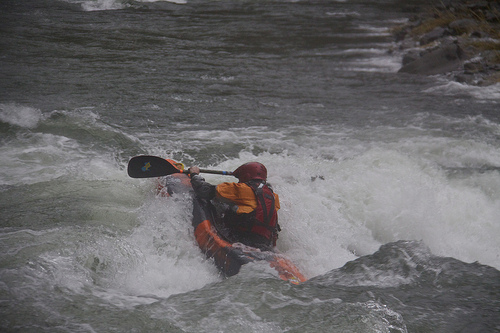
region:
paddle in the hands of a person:
[129, 152, 237, 178]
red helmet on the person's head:
[237, 159, 265, 178]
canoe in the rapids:
[182, 164, 302, 281]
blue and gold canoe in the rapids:
[190, 176, 305, 288]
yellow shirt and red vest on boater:
[213, 183, 279, 243]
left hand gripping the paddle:
[187, 165, 199, 173]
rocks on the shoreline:
[390, 16, 497, 88]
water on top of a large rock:
[16, 240, 497, 331]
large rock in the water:
[25, 238, 497, 331]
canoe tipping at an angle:
[192, 171, 302, 283]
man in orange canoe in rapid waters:
[122, 134, 312, 302]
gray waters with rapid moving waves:
[5, 2, 491, 324]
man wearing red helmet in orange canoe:
[230, 159, 269, 181]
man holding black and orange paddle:
[116, 147, 248, 183]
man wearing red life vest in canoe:
[230, 183, 281, 242]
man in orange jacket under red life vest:
[192, 178, 287, 244]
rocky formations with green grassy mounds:
[345, 9, 499, 98]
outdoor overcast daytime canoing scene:
[11, 0, 496, 326]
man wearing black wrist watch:
[187, 173, 202, 175]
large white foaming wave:
[17, 115, 493, 319]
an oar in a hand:
[119, 147, 239, 182]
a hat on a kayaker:
[233, 154, 269, 196]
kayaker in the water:
[129, 136, 314, 310]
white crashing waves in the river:
[310, 163, 389, 236]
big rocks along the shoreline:
[408, 15, 483, 98]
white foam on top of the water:
[16, 88, 119, 173]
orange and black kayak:
[185, 203, 321, 300]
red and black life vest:
[230, 182, 288, 232]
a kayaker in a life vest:
[193, 161, 294, 253]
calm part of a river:
[147, 22, 242, 64]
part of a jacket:
[258, 157, 263, 172]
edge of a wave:
[337, 245, 344, 266]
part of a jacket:
[256, 187, 261, 208]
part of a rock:
[353, 90, 384, 152]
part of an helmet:
[244, 177, 246, 178]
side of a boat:
[271, 255, 286, 281]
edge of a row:
[180, 173, 191, 192]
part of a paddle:
[209, 179, 210, 194]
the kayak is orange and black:
[162, 153, 309, 290]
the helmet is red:
[234, 162, 279, 184]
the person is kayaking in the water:
[105, 106, 329, 282]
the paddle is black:
[125, 151, 233, 186]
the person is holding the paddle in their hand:
[124, 148, 282, 250]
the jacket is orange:
[213, 182, 282, 225]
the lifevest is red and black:
[245, 179, 280, 245]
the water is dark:
[233, 77, 419, 148]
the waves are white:
[295, 153, 450, 234]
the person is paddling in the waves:
[101, 133, 428, 258]